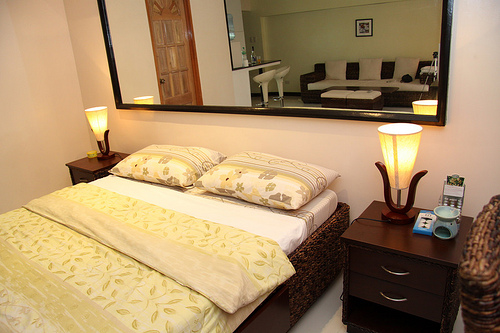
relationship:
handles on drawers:
[387, 262, 408, 285] [343, 126, 468, 331]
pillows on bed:
[106, 126, 348, 232] [0, 136, 356, 330]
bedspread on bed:
[70, 170, 338, 257] [0, 136, 356, 330]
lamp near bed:
[383, 122, 409, 188] [0, 136, 356, 330]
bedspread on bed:
[31, 168, 287, 297] [0, 136, 356, 330]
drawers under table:
[343, 126, 468, 331] [343, 168, 466, 252]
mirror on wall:
[126, 0, 446, 94] [450, 13, 494, 134]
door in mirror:
[142, 8, 208, 93] [126, 0, 446, 94]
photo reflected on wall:
[356, 21, 370, 38] [275, 21, 449, 67]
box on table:
[410, 208, 434, 247] [343, 168, 466, 252]